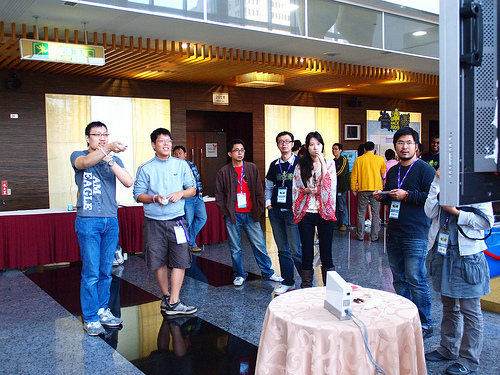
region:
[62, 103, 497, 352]
Group of people looking at TV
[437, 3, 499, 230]
This is a TV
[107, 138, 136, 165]
Man is pointing wii remote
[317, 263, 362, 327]
This is a wii on a table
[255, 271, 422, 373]
Pink tablecloth on table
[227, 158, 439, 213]
People are wearing lanyards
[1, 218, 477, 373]
Grey and black marble floor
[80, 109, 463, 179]
People watching wii on TV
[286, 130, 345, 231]
Woman with red sweater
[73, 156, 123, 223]
Man has American Eagle t-shirt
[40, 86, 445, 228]
many people in photo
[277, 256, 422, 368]
table in front of people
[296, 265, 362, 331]
item on the table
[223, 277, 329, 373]
sheet on the table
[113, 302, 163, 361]
reflection on the ground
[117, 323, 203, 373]
reflection of a person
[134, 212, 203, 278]
shorts on the person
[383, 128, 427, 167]
head of a man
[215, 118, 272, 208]
man in a red shirt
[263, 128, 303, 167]
man wearing pair of glasses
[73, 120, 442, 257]
people playing video games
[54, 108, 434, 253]
people playing nintendo wii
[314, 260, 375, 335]
wii console on the table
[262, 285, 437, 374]
pink table cloth on the table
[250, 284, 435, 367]
the table is round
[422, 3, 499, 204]
the television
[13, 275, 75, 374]
the floor is marble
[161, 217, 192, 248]
the name tag on the shorts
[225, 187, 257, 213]
the name tag around the neck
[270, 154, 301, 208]
the name tag around the neck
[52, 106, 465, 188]
People looking at TV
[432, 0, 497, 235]
This is a tv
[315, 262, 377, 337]
Wii sitting on the table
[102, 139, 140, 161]
Man pointing a wii remote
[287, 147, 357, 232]
Woman has red and white sweater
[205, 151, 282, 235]
Man has hands in his pocket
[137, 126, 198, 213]
Man holding wii remote and smiling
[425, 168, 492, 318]
Woman standing behind TV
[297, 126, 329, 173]
Woman has hand on mouth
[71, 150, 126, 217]
blue and white tee shirt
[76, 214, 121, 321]
medium blue denim jeans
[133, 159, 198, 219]
blue cotton tee shirt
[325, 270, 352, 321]
video game console on table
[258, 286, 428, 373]
pink cotton table cloth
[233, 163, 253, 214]
red cotton tee shirt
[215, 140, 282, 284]
man wearing brown jacket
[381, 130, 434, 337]
man wearing blue sweater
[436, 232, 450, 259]
identification tag on lanyard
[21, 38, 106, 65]
sign hanging on ceiling